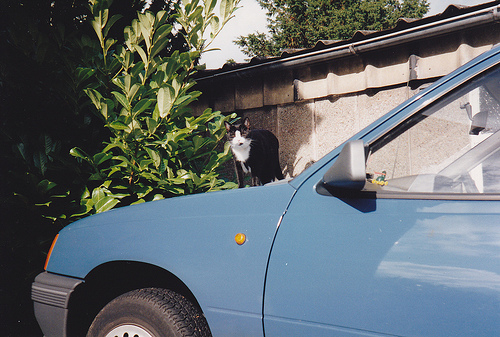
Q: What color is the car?
A: Blue.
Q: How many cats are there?
A: One.